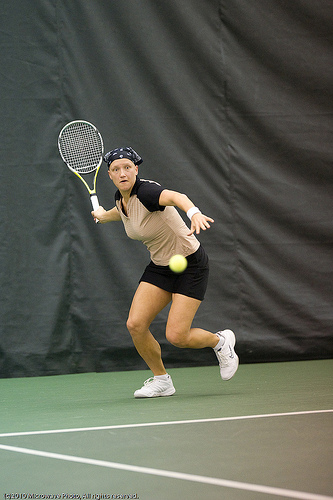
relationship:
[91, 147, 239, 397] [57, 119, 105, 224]
girl playing racket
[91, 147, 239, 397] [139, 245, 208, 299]
girl has a shorts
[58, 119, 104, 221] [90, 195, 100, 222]
racket has handle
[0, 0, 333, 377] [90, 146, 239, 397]
tarp behind woman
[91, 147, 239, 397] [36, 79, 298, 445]
girl playing tennis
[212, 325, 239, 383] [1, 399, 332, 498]
shoe above ground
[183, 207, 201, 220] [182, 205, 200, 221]
wrist band on wrist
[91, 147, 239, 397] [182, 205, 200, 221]
girl has wrist